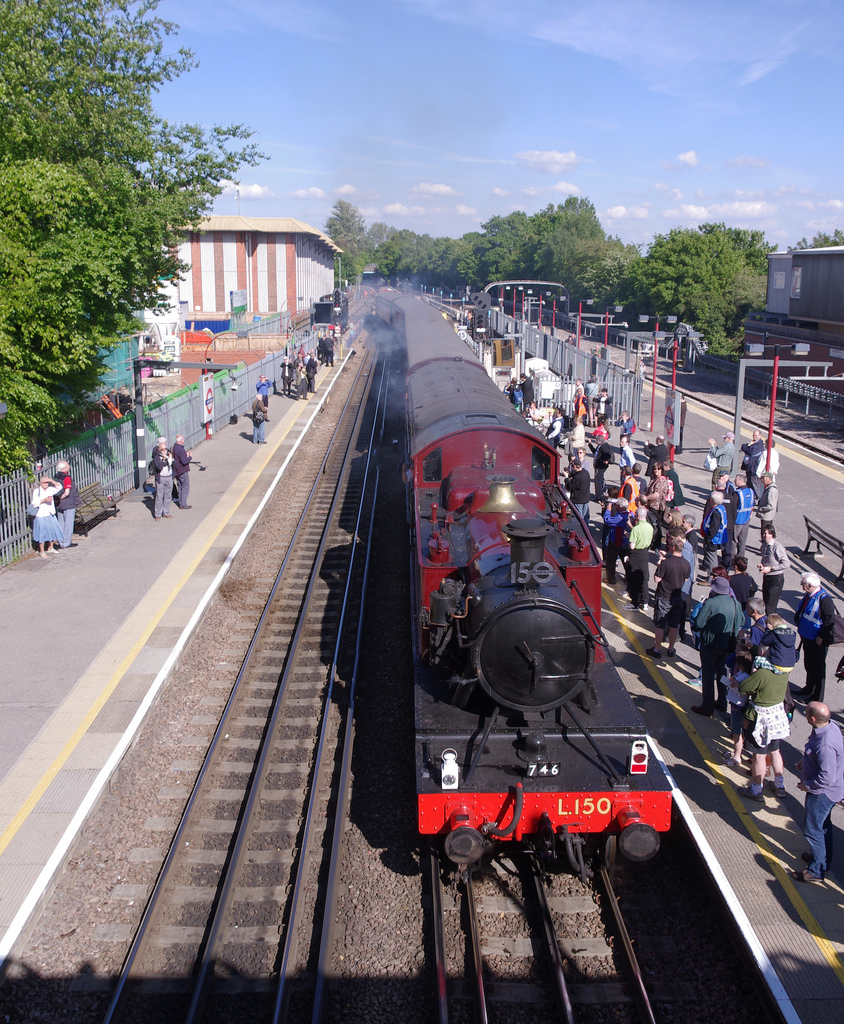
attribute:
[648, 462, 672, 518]
person — standing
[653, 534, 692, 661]
person — standing up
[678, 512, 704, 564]
person — standing up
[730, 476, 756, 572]
person — standing up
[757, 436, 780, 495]
person — standing up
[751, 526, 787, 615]
person — standing up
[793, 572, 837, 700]
person — standing up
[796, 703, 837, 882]
person — standing up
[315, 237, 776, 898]
train — red , black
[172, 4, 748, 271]
sky — blue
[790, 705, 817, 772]
shirt — blue 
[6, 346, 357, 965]
line — white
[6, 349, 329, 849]
line — yellow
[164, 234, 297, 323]
stripes — red, white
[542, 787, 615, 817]
writing — yellow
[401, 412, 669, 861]
engine — BLACK, RED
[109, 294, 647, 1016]
tracks — long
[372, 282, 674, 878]
train — red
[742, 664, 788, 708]
shirt — green